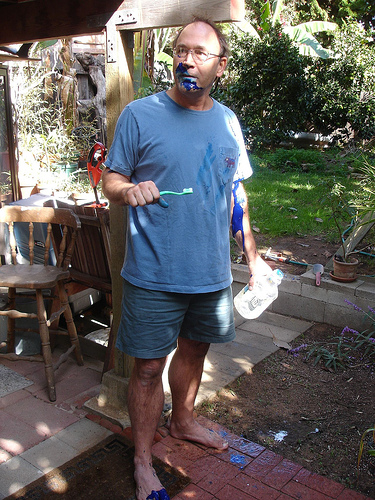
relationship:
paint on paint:
[144, 486, 169, 498] [144, 486, 169, 498]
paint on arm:
[230, 177, 245, 250] [227, 178, 277, 289]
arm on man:
[227, 178, 277, 289] [100, 18, 271, 498]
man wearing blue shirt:
[100, 18, 271, 498] [108, 94, 254, 295]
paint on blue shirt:
[220, 143, 241, 175] [108, 94, 254, 295]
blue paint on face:
[166, 63, 205, 105] [175, 20, 215, 98]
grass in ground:
[244, 150, 373, 251] [224, 140, 372, 293]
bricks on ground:
[250, 449, 272, 468] [0, 147, 373, 498]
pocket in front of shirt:
[219, 148, 244, 181] [218, 142, 233, 173]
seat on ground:
[0, 260, 76, 291] [196, 322, 373, 499]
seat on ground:
[0, 260, 76, 291] [249, 222, 373, 283]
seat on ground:
[0, 260, 76, 291] [7, 433, 204, 498]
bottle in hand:
[227, 264, 285, 324] [247, 256, 273, 292]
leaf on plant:
[291, 33, 337, 59] [142, 1, 371, 62]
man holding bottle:
[100, 18, 271, 498] [232, 253, 288, 314]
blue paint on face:
[171, 61, 206, 98] [170, 24, 219, 95]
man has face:
[100, 18, 271, 498] [170, 24, 219, 95]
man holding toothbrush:
[100, 18, 271, 498] [144, 181, 209, 206]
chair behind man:
[0, 205, 86, 403] [100, 18, 271, 498]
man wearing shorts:
[100, 18, 271, 498] [115, 276, 233, 360]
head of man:
[170, 15, 229, 94] [100, 18, 271, 498]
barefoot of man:
[137, 454, 167, 498] [100, 18, 271, 498]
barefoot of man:
[171, 422, 229, 449] [100, 18, 271, 498]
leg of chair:
[35, 285, 58, 402] [0, 205, 86, 403]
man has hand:
[100, 18, 271, 498] [124, 179, 169, 213]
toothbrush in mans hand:
[162, 169, 194, 229] [124, 179, 169, 213]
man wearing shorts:
[100, 18, 271, 498] [113, 274, 236, 364]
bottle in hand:
[227, 264, 285, 324] [244, 248, 276, 298]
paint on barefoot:
[144, 486, 169, 498] [137, 454, 167, 498]